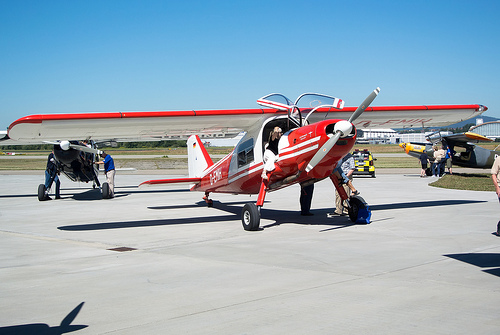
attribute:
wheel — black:
[234, 196, 280, 238]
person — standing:
[97, 144, 127, 188]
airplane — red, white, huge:
[6, 60, 490, 273]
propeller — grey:
[282, 87, 414, 193]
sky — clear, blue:
[8, 10, 498, 165]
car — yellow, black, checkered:
[339, 122, 404, 199]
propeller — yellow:
[394, 124, 450, 180]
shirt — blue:
[89, 137, 123, 176]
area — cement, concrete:
[11, 164, 457, 334]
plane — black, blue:
[42, 118, 132, 211]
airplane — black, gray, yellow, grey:
[383, 78, 497, 192]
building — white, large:
[355, 132, 452, 162]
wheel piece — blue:
[353, 192, 381, 231]